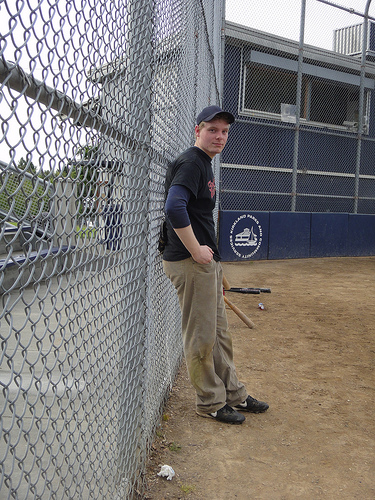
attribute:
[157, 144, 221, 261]
shirt — black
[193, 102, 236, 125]
cap — baseball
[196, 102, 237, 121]
cap — blue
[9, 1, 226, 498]
fence — chain-link, chain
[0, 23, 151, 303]
gate — metal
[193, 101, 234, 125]
hat — white